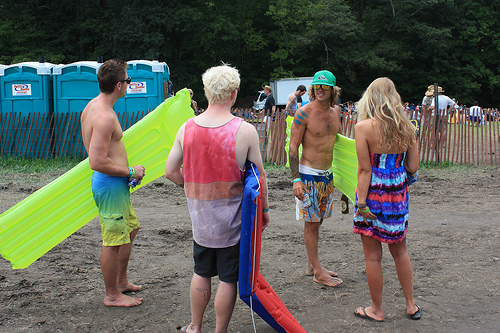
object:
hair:
[356, 77, 418, 153]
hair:
[201, 65, 241, 104]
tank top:
[180, 114, 248, 250]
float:
[1, 81, 205, 269]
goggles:
[314, 83, 334, 88]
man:
[76, 54, 344, 333]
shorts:
[292, 160, 334, 230]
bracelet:
[355, 207, 371, 214]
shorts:
[85, 173, 147, 255]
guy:
[76, 56, 347, 333]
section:
[189, 125, 239, 185]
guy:
[168, 60, 273, 330]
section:
[175, 174, 245, 208]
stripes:
[287, 105, 305, 136]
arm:
[279, 100, 319, 201]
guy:
[286, 65, 356, 304]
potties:
[4, 59, 166, 159]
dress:
[350, 143, 420, 243]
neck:
[193, 103, 237, 121]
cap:
[310, 69, 337, 86]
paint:
[289, 105, 314, 137]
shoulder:
[285, 102, 321, 130]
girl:
[340, 72, 426, 321]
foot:
[354, 303, 384, 323]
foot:
[403, 305, 418, 315]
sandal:
[354, 305, 371, 321]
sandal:
[408, 306, 422, 320]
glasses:
[118, 78, 134, 86]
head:
[311, 86, 334, 101]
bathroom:
[1, 59, 51, 159]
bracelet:
[292, 177, 301, 181]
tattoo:
[192, 283, 210, 303]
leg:
[187, 274, 209, 329]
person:
[79, 59, 449, 333]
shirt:
[261, 96, 275, 118]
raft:
[233, 163, 308, 331]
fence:
[6, 105, 491, 172]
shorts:
[192, 240, 239, 285]